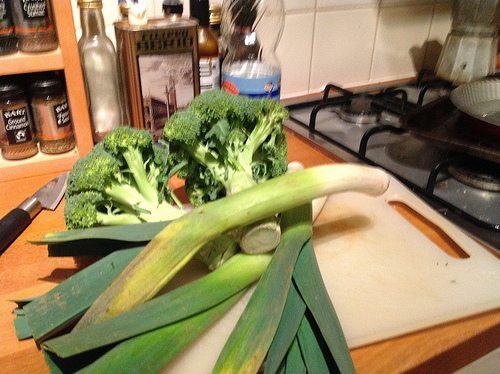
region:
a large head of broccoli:
[162, 98, 327, 261]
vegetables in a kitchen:
[7, 8, 494, 353]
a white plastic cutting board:
[343, 226, 494, 318]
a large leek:
[69, 152, 398, 333]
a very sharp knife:
[5, 167, 90, 245]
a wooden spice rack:
[8, 7, 107, 187]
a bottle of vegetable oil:
[210, 5, 305, 109]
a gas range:
[333, 70, 497, 187]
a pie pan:
[444, 65, 491, 167]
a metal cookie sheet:
[392, 108, 498, 178]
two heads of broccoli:
[65, 92, 287, 272]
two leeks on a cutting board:
[14, 163, 386, 372]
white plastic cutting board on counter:
[164, 167, 498, 372]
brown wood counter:
[2, 145, 498, 370]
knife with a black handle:
[2, 175, 69, 265]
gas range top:
[286, 84, 497, 256]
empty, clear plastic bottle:
[221, 1, 281, 111]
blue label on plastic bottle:
[221, 69, 281, 96]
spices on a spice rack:
[1, 0, 88, 177]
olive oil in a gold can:
[117, 17, 200, 152]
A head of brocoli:
[60, 123, 237, 270]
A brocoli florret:
[103, 124, 153, 155]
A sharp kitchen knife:
[1, 170, 71, 252]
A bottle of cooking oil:
[219, 1, 282, 98]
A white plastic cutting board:
[154, 170, 499, 372]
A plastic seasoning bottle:
[29, 71, 74, 155]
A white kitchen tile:
[308, 4, 381, 91]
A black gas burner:
[282, 81, 422, 155]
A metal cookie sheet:
[401, 88, 499, 159]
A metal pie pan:
[454, 76, 499, 127]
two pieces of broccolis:
[72, 82, 304, 258]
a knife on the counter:
[0, 165, 85, 285]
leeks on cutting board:
[15, 160, 390, 371]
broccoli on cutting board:
[64, 91, 294, 266]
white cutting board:
[156, 173, 498, 370]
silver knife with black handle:
[0, 169, 69, 256]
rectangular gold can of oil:
[115, 8, 200, 134]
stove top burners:
[285, 78, 497, 252]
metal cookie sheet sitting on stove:
[397, 82, 499, 165]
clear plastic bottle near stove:
[219, 1, 285, 119]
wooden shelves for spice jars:
[0, 1, 91, 183]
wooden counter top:
[0, 110, 498, 372]